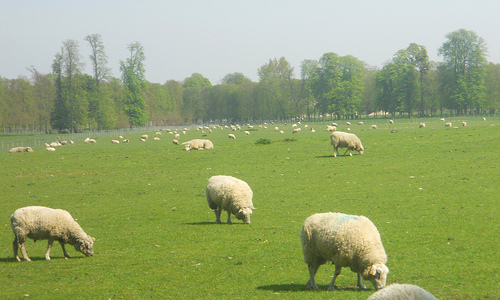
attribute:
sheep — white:
[209, 175, 254, 224]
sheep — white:
[329, 131, 362, 156]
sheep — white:
[183, 136, 213, 153]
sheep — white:
[202, 169, 262, 231]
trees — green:
[1, 30, 497, 132]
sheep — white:
[199, 173, 258, 228]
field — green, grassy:
[55, 73, 497, 299]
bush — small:
[250, 133, 274, 149]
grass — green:
[360, 158, 475, 253]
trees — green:
[431, 24, 493, 117]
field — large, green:
[0, 111, 497, 298]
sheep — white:
[286, 204, 406, 296]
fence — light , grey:
[3, 115, 310, 145]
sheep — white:
[366, 121, 379, 130]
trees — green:
[52, 36, 153, 129]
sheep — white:
[8, 203, 98, 264]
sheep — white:
[298, 206, 388, 293]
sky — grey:
[39, 11, 499, 64]